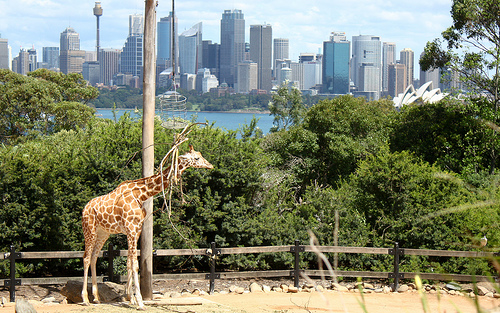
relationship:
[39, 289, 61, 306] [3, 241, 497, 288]
rock lines fence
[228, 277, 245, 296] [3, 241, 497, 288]
rock lines fence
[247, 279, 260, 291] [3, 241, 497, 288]
rock lines fence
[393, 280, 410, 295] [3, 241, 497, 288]
rock lines fence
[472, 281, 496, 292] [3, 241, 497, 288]
rock lines fence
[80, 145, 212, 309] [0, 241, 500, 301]
giraffe standing in fence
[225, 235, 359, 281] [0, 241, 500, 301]
fence around fence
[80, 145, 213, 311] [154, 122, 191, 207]
giraffe eat hay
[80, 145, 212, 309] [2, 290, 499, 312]
giraffe stands ground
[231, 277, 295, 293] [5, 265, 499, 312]
rocks on ground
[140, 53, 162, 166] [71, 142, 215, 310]
pole near giraffe.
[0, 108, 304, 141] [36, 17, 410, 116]
water near buildings.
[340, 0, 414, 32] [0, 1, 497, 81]
cloud in sky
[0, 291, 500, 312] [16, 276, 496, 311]
dirt on ground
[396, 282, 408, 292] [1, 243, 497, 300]
rock are below fence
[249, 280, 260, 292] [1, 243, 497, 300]
rock are below fence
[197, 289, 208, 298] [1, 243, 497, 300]
rock are below fence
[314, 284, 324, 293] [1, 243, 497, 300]
rock are below fence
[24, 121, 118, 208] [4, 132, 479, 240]
tree are on hillside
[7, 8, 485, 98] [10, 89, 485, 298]
city behind zoo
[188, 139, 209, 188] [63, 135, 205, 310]
face of a giraffe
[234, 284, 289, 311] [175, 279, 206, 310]
dirt on ground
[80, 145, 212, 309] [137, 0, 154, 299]
giraffe near post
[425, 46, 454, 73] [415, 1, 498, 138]
leaves on tree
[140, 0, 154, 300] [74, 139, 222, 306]
pole near giraffe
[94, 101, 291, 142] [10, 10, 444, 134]
water near city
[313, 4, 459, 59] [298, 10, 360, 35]
clouds in sky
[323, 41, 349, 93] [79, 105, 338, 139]
building near water